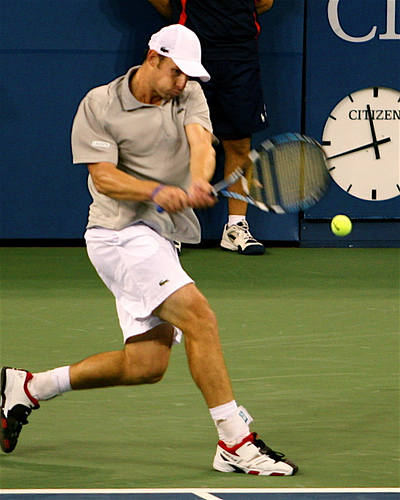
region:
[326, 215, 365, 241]
Tennis ball in the air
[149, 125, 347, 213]
Tennis racket in the man's hands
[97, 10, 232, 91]
White hat on the man's head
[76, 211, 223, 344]
White shorts on the man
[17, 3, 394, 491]
Photo taken at a tennis match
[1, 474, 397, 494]
White lines on the court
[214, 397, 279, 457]
The man is wearing an ankle brace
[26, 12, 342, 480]
Tennis player hitting a ball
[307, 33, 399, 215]
Clock face on the wall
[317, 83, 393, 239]
Photo taken at 11:43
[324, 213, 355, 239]
Bright Yellow Tennis Ball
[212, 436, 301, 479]
red, white, and black tennis shoes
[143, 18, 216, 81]
white baseball cap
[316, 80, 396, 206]
Giant Citizen Clock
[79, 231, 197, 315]
White Nike Shorts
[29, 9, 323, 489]
Tennis player making a move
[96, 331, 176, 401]
bending at the knee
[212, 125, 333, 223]
Blue, Black, And White Tennis Rack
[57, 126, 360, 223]
Mid hit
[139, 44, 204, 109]
blowing his cheecks out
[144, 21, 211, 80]
white hat on a tennis player's head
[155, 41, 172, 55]
black design on a white hat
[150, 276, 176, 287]
black design on white shorts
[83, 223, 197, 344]
white shorts on a tennis player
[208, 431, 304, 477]
red white and black shoes on a tennis player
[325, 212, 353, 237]
green tennis ball in the air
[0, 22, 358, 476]
tennis player swinging his racket at a ball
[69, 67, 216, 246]
gray shirt on a tennis player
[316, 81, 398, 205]
black and white clock on a blue wall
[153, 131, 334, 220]
blue black and white tennis racket in a man's hand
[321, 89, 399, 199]
a large black and white clock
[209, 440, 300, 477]
a man's tennis shoe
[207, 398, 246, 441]
a man's white sock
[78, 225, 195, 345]
a man's white shorts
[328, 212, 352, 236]
a small green tennis ball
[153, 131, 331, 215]
a blue and white racket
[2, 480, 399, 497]
a long white line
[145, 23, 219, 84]
a white baseball cap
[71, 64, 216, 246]
a man's gray shirt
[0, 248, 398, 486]
part of a tennis court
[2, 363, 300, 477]
Man is wearing shoes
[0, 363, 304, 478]
Man is wearing white, red, and black shoes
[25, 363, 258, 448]
Man is wearing socks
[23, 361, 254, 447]
Man is wearing white socks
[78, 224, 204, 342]
Man is wearing shorts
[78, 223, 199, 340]
Man is wearing white shorts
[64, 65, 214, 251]
Man is wearing a shirt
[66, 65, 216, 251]
Man is wearing a gray shirt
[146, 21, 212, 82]
Man is wearing a hat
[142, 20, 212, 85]
Man is wearing a white hat